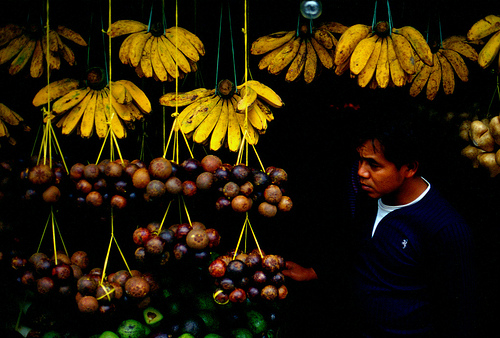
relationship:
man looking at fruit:
[345, 129, 467, 338] [116, 151, 305, 274]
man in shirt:
[345, 129, 467, 338] [349, 208, 494, 322]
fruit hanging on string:
[22, 162, 289, 217] [237, 12, 261, 166]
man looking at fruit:
[328, 124, 477, 336] [2, 128, 347, 333]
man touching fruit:
[345, 129, 467, 338] [199, 229, 319, 307]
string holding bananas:
[367, 3, 397, 38] [332, 18, 437, 91]